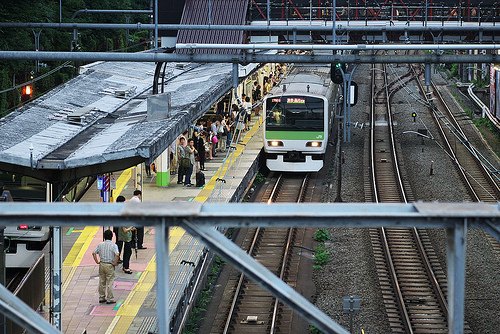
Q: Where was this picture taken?
A: A train station.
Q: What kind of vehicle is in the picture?
A: One.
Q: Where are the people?
A: On the platform.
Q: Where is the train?
A: On the tracks.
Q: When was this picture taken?
A: Day time.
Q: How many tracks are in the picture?
A: Three.